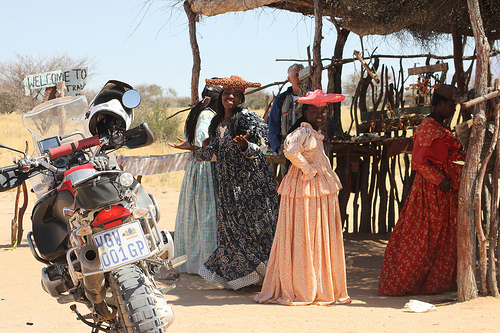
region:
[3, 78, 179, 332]
motorcycle is parked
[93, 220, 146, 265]
white metal license plate above thick black tire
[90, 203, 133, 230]
red taillight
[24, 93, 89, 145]
windshield on motorcycle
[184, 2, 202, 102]
wood post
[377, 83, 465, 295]
woman wearing a red dress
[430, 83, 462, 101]
hat on woman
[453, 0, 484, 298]
a gnarled wooden post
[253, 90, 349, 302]
woman wearing a long peach dress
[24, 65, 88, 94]
white sign behind motorcycle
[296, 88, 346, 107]
pink hat on woman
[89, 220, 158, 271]
blue and white motorcycle plate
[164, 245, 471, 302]
women's dresses drag on ground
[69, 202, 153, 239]
tail lights for motorcycle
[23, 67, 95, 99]
welcome sign on post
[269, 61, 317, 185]
elderly white man in background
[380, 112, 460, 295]
red flowered dress with long sleeves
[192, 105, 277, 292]
black and white patterned dress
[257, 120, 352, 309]
long peach colored dress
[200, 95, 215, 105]
pink ribbon in hair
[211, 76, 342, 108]
the woman wear hats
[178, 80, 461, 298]
the women wears long dresses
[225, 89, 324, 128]
the women are smiling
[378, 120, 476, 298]
the woman wears a red dress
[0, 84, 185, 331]
the bike is parked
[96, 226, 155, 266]
the bike has license plate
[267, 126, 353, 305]
the woman has an orange dress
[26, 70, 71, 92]
the sign says welcome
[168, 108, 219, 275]
the woman has a blue dress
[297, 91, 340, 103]
the woman has a red hat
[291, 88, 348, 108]
red hat on woman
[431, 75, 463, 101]
muted brown hat with red accents on woman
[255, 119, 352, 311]
long peach dress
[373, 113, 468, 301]
long red and green dress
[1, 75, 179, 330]
black motorcycle with red handlebars parked on dirt ground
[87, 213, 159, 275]
blue and white license plate on back of motorcycle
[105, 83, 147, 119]
rear view mirror on side of motorcycle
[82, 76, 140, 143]
black and white helmet on front of motorcycle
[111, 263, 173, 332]
tread on black tire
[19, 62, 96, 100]
black and white welcome sign on stick in road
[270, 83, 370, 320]
woman wearing a hat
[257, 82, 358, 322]
woman wearing a dress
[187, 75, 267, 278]
woman wearing a hat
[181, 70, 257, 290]
woman wearing a dress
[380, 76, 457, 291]
woman wearing a hat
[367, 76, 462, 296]
woman wearing a dress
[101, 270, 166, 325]
tire of a cycle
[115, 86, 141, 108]
mirror of a cycle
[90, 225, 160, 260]
license plate on a motor cycle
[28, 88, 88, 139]
window on a cycle